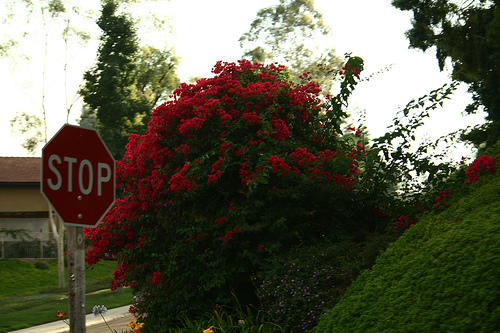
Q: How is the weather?
A: It is clear.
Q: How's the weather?
A: It is clear.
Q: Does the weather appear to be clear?
A: Yes, it is clear.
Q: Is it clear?
A: Yes, it is clear.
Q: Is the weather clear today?
A: Yes, it is clear.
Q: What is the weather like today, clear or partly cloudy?
A: It is clear.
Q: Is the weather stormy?
A: No, it is clear.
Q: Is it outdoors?
A: Yes, it is outdoors.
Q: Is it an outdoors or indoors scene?
A: It is outdoors.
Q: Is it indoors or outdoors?
A: It is outdoors.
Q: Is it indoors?
A: No, it is outdoors.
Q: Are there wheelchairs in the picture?
A: No, there are no wheelchairs.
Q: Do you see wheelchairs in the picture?
A: No, there are no wheelchairs.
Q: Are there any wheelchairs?
A: No, there are no wheelchairs.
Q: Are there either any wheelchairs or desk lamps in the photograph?
A: No, there are no wheelchairs or desk lamps.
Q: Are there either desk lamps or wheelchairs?
A: No, there are no wheelchairs or desk lamps.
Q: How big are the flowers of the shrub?
A: The flowers are tiny.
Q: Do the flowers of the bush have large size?
A: No, the flowers are tiny.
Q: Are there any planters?
A: No, there are no planters.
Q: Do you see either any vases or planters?
A: No, there are no planters or vases.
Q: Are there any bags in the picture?
A: No, there are no bags.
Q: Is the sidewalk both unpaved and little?
A: No, the sidewalk is little but paved.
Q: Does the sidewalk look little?
A: Yes, the sidewalk is little.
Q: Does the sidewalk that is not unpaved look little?
A: Yes, the side walk is little.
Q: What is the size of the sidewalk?
A: The sidewalk is little.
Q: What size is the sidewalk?
A: The sidewalk is little.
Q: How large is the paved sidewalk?
A: The side walk is little.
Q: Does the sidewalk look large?
A: No, the sidewalk is little.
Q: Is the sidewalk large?
A: No, the sidewalk is little.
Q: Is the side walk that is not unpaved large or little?
A: The side walk is little.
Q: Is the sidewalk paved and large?
A: No, the sidewalk is paved but little.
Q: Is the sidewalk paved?
A: Yes, the sidewalk is paved.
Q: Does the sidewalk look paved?
A: Yes, the sidewalk is paved.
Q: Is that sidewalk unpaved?
A: No, the sidewalk is paved.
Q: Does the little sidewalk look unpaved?
A: No, the side walk is paved.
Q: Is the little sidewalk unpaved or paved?
A: The sidewalk is paved.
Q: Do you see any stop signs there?
A: Yes, there is a stop sign.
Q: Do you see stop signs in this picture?
A: Yes, there is a stop sign.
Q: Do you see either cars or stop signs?
A: Yes, there is a stop sign.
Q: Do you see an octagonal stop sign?
A: Yes, there is an octagonal stop sign.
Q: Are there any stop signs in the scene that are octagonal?
A: Yes, there is a stop sign that is octagonal.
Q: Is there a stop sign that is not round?
A: Yes, there is a octagonal stop sign.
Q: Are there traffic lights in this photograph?
A: No, there are no traffic lights.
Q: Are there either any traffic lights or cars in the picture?
A: No, there are no traffic lights or cars.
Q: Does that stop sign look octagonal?
A: Yes, the stop sign is octagonal.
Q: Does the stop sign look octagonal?
A: Yes, the stop sign is octagonal.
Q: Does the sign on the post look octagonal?
A: Yes, the stop sign is octagonal.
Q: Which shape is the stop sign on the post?
A: The stop sign is octagonal.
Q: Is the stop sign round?
A: No, the stop sign is octagonal.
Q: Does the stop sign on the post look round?
A: No, the stop sign is octagonal.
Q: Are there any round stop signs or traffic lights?
A: No, there is a stop sign but it is octagonal.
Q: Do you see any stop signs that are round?
A: No, there is a stop sign but it is octagonal.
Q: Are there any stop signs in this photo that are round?
A: No, there is a stop sign but it is octagonal.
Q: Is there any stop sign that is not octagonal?
A: No, there is a stop sign but it is octagonal.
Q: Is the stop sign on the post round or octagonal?
A: The stop sign is octagonal.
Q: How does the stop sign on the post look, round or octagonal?
A: The stop sign is octagonal.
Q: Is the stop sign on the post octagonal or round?
A: The stop sign is octagonal.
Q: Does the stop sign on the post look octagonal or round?
A: The stop sign is octagonal.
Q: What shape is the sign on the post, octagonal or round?
A: The stop sign is octagonal.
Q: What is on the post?
A: The stop sign is on the post.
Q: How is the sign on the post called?
A: The sign is a stop sign.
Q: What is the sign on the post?
A: The sign is a stop sign.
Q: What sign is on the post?
A: The sign is a stop sign.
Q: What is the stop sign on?
A: The stop sign is on the post.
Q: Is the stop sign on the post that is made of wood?
A: Yes, the stop sign is on the post.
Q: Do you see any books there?
A: No, there are no books.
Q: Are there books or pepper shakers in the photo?
A: No, there are no books or pepper shakers.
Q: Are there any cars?
A: No, there are no cars.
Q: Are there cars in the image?
A: No, there are no cars.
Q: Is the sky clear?
A: Yes, the sky is clear.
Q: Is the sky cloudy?
A: No, the sky is clear.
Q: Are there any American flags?
A: No, there are no American flags.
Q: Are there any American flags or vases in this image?
A: No, there are no American flags or vases.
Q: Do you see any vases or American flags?
A: No, there are no American flags or vases.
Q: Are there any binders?
A: No, there are no binders.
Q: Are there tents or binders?
A: No, there are no binders or tents.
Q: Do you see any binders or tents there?
A: No, there are no binders or tents.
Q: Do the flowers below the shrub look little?
A: Yes, the flowers are little.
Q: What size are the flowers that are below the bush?
A: The flowers are little.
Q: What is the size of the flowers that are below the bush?
A: The flowers are little.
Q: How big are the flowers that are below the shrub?
A: The flowers are little.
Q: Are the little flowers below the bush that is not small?
A: Yes, the flowers are below the bush.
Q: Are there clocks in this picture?
A: No, there are no clocks.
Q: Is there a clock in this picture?
A: No, there are no clocks.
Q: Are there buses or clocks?
A: No, there are no clocks or buses.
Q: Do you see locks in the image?
A: No, there are no locks.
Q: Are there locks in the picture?
A: No, there are no locks.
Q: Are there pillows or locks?
A: No, there are no locks or pillows.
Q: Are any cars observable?
A: No, there are no cars.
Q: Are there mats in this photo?
A: No, there are no mats.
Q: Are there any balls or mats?
A: No, there are no mats or balls.